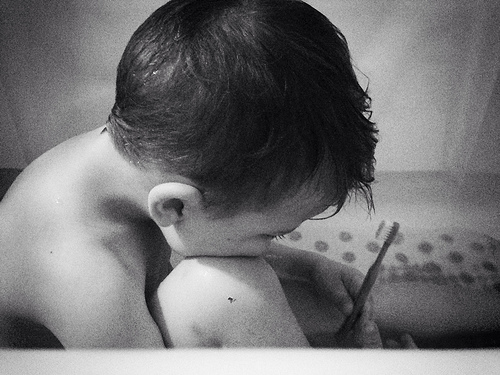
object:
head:
[105, 0, 376, 257]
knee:
[176, 256, 282, 334]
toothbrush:
[332, 221, 395, 344]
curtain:
[369, 0, 499, 207]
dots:
[328, 223, 500, 336]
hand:
[315, 254, 371, 322]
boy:
[0, 0, 500, 350]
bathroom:
[0, 0, 500, 349]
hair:
[100, 0, 384, 223]